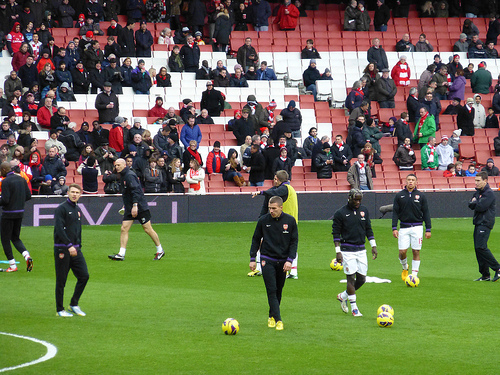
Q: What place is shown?
A: It is a field.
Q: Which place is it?
A: It is a field.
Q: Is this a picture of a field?
A: Yes, it is showing a field.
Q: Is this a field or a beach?
A: It is a field.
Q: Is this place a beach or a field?
A: It is a field.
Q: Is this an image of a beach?
A: No, the picture is showing a field.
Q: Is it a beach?
A: No, it is a field.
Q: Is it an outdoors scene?
A: Yes, it is outdoors.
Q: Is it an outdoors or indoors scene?
A: It is outdoors.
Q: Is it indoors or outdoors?
A: It is outdoors.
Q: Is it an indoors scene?
A: No, it is outdoors.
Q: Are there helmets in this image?
A: No, there are no helmets.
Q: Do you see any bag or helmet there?
A: No, there are no helmets or bags.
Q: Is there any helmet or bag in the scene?
A: No, there are no helmets or bags.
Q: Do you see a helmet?
A: No, there are no helmets.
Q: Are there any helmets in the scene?
A: No, there are no helmets.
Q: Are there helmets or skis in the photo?
A: No, there are no helmets or skis.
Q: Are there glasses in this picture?
A: No, there are no glasses.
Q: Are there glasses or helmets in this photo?
A: No, there are no glasses or helmets.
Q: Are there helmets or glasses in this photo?
A: No, there are no glasses or helmets.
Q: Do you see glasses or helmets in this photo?
A: No, there are no glasses or helmets.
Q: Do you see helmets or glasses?
A: No, there are no glasses or helmets.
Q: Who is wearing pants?
A: The man is wearing pants.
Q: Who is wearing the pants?
A: The man is wearing pants.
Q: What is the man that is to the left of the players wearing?
A: The man is wearing trousers.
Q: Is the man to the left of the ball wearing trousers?
A: Yes, the man is wearing trousers.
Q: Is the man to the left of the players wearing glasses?
A: No, the man is wearing trousers.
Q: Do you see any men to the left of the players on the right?
A: Yes, there is a man to the left of the players.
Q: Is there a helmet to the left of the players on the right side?
A: No, there is a man to the left of the players.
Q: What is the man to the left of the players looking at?
A: The man is looking at the ball.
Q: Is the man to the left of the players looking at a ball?
A: Yes, the man is looking at a ball.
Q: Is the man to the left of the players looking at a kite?
A: No, the man is looking at a ball.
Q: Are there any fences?
A: No, there are no fences.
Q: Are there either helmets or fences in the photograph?
A: No, there are no fences or helmets.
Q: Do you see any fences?
A: No, there are no fences.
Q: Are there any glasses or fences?
A: No, there are no fences or glasses.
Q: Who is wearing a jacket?
A: The man is wearing a jacket.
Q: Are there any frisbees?
A: No, there are no frisbees.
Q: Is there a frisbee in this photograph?
A: No, there are no frisbees.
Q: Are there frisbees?
A: No, there are no frisbees.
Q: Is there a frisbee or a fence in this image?
A: No, there are no frisbees or fences.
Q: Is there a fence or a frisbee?
A: No, there are no frisbees or fences.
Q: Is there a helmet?
A: No, there are no helmets.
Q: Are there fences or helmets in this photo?
A: No, there are no helmets or fences.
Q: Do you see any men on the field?
A: Yes, there is a man on the field.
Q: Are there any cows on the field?
A: No, there is a man on the field.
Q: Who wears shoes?
A: The man wears shoes.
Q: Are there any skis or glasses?
A: No, there are no skis or glasses.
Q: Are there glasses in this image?
A: No, there are no glasses.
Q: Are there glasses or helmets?
A: No, there are no glasses or helmets.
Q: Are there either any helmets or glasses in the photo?
A: No, there are no glasses or helmets.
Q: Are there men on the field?
A: Yes, there is a man on the field.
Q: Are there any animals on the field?
A: No, there is a man on the field.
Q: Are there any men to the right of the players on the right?
A: Yes, there is a man to the right of the players.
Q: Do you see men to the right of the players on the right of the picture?
A: Yes, there is a man to the right of the players.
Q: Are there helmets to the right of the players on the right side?
A: No, there is a man to the right of the players.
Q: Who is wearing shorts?
A: The man is wearing shorts.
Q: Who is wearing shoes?
A: The man is wearing shoes.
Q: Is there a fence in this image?
A: No, there are no fences.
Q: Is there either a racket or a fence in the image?
A: No, there are no fences or rackets.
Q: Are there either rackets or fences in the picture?
A: No, there are no fences or rackets.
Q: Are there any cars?
A: No, there are no cars.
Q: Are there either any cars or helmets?
A: No, there are no cars or helmets.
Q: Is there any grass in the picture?
A: Yes, there is grass.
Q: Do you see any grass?
A: Yes, there is grass.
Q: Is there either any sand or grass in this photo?
A: Yes, there is grass.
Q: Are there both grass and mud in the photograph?
A: No, there is grass but no mud.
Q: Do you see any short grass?
A: Yes, there is short grass.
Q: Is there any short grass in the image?
A: Yes, there is short grass.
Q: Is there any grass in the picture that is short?
A: Yes, there is grass that is short.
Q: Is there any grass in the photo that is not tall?
A: Yes, there is short grass.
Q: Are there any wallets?
A: No, there are no wallets.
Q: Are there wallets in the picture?
A: No, there are no wallets.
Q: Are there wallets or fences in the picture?
A: No, there are no wallets or fences.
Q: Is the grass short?
A: Yes, the grass is short.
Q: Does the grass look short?
A: Yes, the grass is short.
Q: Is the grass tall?
A: No, the grass is short.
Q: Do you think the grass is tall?
A: No, the grass is short.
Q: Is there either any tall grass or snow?
A: No, there is grass but it is short.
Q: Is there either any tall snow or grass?
A: No, there is grass but it is short.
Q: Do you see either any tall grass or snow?
A: No, there is grass but it is short.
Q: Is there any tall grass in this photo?
A: No, there is grass but it is short.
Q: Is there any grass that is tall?
A: No, there is grass but it is short.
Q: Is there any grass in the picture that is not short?
A: No, there is grass but it is short.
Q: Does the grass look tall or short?
A: The grass is short.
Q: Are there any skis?
A: No, there are no skis.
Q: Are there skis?
A: No, there are no skis.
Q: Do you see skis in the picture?
A: No, there are no skis.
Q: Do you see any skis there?
A: No, there are no skis.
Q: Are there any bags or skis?
A: No, there are no skis or bags.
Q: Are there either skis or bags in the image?
A: No, there are no skis or bags.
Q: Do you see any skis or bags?
A: No, there are no skis or bags.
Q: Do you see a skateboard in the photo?
A: No, there are no skateboards.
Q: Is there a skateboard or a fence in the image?
A: No, there are no skateboards or fences.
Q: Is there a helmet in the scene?
A: No, there are no helmets.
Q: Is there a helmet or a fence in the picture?
A: No, there are no helmets or fences.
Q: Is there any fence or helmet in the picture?
A: No, there are no helmets or fences.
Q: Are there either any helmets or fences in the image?
A: No, there are no helmets or fences.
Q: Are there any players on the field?
A: Yes, there are players on the field.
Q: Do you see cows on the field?
A: No, there are players on the field.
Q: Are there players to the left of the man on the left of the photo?
A: Yes, there are players to the left of the man.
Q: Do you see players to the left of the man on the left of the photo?
A: Yes, there are players to the left of the man.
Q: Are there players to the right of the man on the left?
A: No, the players are to the left of the man.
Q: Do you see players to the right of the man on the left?
A: No, the players are to the left of the man.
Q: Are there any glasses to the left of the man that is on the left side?
A: No, there are players to the left of the man.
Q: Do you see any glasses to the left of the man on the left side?
A: No, there are players to the left of the man.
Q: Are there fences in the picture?
A: No, there are no fences.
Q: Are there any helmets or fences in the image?
A: No, there are no fences or helmets.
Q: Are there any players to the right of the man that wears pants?
A: Yes, there are players to the right of the man.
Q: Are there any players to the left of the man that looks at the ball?
A: No, the players are to the right of the man.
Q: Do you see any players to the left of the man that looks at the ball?
A: No, the players are to the right of the man.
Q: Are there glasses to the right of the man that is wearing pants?
A: No, there are players to the right of the man.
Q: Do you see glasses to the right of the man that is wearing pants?
A: No, there are players to the right of the man.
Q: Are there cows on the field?
A: No, there are players on the field.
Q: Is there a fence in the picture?
A: No, there are no fences.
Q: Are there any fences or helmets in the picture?
A: No, there are no fences or helmets.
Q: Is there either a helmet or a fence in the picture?
A: No, there are no fences or helmets.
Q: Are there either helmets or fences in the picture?
A: No, there are no fences or helmets.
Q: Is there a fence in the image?
A: No, there are no fences.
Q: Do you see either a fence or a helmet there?
A: No, there are no fences or helmets.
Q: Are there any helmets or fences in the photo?
A: No, there are no fences or helmets.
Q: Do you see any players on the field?
A: Yes, there are players on the field.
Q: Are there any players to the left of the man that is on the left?
A: Yes, there are players to the left of the man.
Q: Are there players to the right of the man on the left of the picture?
A: No, the players are to the left of the man.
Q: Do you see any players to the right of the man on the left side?
A: No, the players are to the left of the man.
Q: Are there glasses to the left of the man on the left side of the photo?
A: No, there are players to the left of the man.